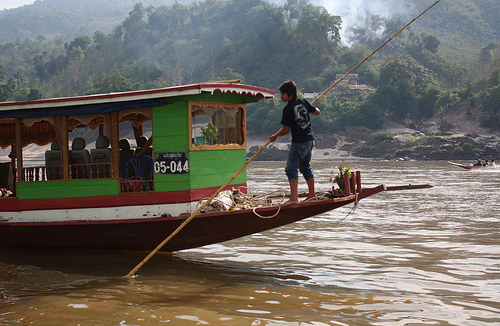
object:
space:
[217, 194, 318, 211]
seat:
[88, 146, 118, 179]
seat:
[66, 148, 94, 176]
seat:
[43, 148, 69, 179]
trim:
[198, 84, 278, 101]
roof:
[0, 81, 277, 128]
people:
[69, 136, 93, 178]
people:
[490, 156, 498, 166]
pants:
[284, 138, 317, 182]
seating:
[17, 161, 142, 192]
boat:
[444, 154, 499, 171]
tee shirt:
[280, 97, 318, 143]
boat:
[0, 79, 385, 252]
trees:
[69, 43, 87, 66]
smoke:
[264, 0, 400, 52]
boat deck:
[198, 169, 388, 227]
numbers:
[182, 159, 189, 172]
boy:
[268, 78, 319, 208]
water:
[0, 160, 499, 325]